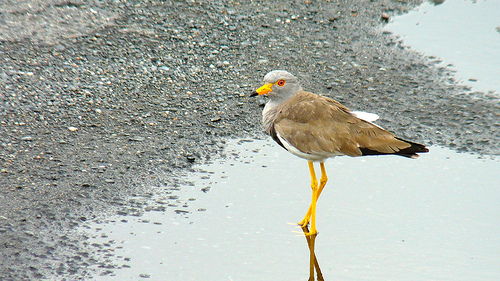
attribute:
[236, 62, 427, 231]
bird — white, brown, black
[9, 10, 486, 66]
beach — pebbly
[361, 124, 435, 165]
tail feathers — black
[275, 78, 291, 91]
eyes — red, orange, black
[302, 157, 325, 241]
legs — long, yellow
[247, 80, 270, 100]
beak — yellow, black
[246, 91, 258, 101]
tip — black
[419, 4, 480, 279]
shore — grey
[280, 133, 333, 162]
belly — white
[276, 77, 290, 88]
eye — red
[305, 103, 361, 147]
feathers — tan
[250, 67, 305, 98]
head — gray